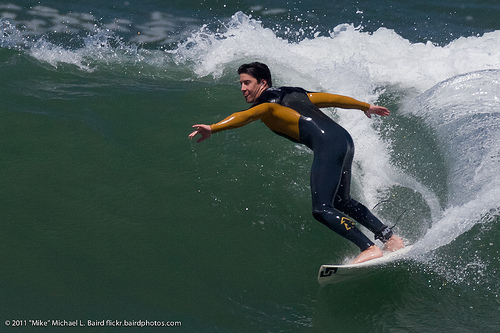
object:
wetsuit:
[208, 87, 391, 253]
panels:
[211, 102, 299, 137]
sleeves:
[309, 92, 369, 113]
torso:
[260, 106, 350, 165]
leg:
[313, 145, 380, 264]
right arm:
[307, 92, 370, 112]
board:
[318, 242, 427, 286]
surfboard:
[316, 235, 431, 284]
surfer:
[188, 60, 415, 283]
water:
[3, 3, 498, 329]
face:
[238, 72, 260, 103]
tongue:
[243, 94, 249, 97]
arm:
[212, 104, 267, 136]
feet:
[343, 244, 383, 264]